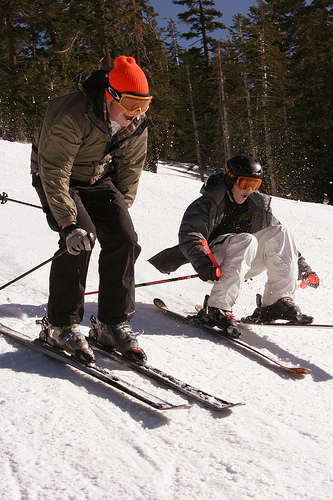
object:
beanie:
[105, 56, 149, 98]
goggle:
[106, 83, 153, 114]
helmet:
[223, 151, 264, 202]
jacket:
[31, 71, 150, 231]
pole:
[1, 232, 95, 291]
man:
[29, 56, 151, 367]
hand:
[64, 228, 93, 259]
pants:
[206, 223, 300, 311]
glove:
[62, 224, 95, 256]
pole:
[84, 266, 222, 295]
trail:
[1, 139, 331, 500]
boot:
[199, 295, 241, 339]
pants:
[32, 180, 143, 328]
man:
[178, 155, 319, 339]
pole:
[1, 194, 45, 210]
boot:
[258, 295, 313, 326]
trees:
[174, 0, 227, 66]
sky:
[138, 0, 330, 58]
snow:
[1, 138, 333, 500]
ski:
[1, 321, 190, 411]